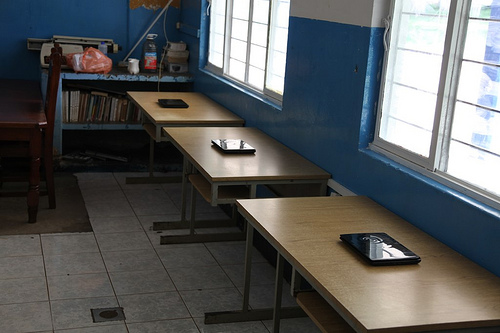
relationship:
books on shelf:
[61, 90, 142, 122] [54, 75, 179, 152]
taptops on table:
[154, 93, 424, 273] [280, 211, 326, 247]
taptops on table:
[154, 93, 424, 273] [176, 129, 206, 151]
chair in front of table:
[2, 39, 63, 210] [0, 77, 50, 226]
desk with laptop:
[232, 197, 499, 331] [339, 232, 421, 265]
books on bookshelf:
[61, 90, 142, 122] [59, 84, 139, 167]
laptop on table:
[341, 232, 421, 265] [201, 194, 498, 331]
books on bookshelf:
[61, 90, 142, 122] [47, 71, 191, 167]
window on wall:
[367, 0, 499, 210] [172, 0, 499, 270]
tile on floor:
[59, 223, 227, 307] [1, 149, 318, 331]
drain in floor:
[90, 310, 121, 321] [10, 173, 276, 330]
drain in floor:
[95, 307, 122, 322] [10, 173, 276, 330]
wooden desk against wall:
[203, 192, 498, 332] [333, 142, 498, 267]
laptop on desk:
[339, 232, 421, 265] [232, 197, 499, 331]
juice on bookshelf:
[141, 32, 158, 78] [42, 70, 192, 171]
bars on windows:
[394, 5, 497, 164] [353, 4, 495, 231]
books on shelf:
[61, 90, 142, 122] [45, 47, 212, 171]